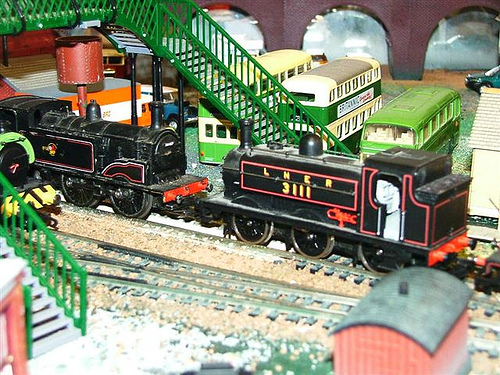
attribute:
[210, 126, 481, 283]
engine — toy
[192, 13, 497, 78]
archways — red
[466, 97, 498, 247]
building —  WHITE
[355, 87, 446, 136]
green toy — car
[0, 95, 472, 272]
train — plastic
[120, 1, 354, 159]
stairs — green , short , long 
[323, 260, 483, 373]
barn — red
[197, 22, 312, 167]
bus — green, double decker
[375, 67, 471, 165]
bus — green 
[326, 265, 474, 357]
roof — black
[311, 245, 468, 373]
building — small, red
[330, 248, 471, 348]
roof — black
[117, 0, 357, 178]
stairs — GREEN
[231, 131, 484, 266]
car — Black 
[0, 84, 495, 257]
train — black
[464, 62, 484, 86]
car — green, little